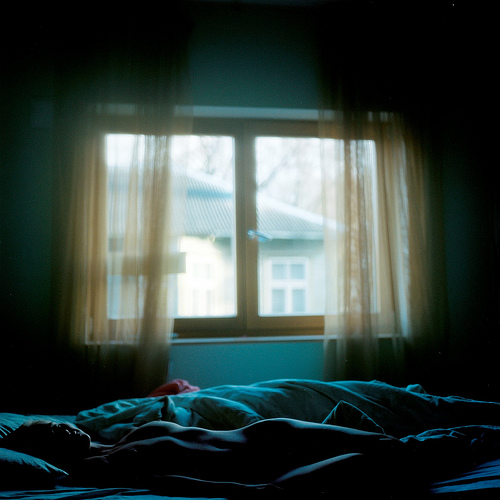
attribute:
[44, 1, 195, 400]
curtains — brown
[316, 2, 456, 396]
curtains — brown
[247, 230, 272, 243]
handle — silver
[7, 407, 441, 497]
woman — nude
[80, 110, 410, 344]
window — beautiful 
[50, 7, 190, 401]
curtain — sheer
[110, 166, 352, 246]
roof — black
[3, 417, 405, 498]
woman — nude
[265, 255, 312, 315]
window — white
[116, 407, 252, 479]
woman — naked 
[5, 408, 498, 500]
person — nude